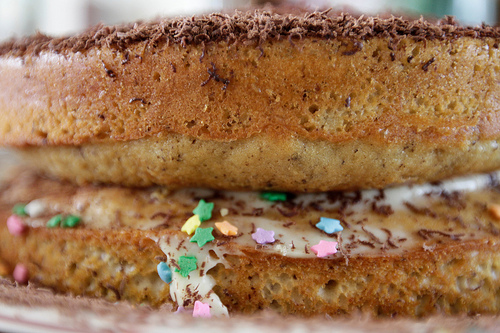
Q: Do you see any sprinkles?
A: Yes, there are sprinkles.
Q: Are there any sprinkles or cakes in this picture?
A: Yes, there are sprinkles.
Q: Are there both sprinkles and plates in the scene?
A: No, there are sprinkles but no plates.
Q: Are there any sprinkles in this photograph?
A: Yes, there are sprinkles.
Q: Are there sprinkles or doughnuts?
A: Yes, there are sprinkles.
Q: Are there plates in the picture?
A: No, there are no plates.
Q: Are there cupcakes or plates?
A: No, there are no plates or cupcakes.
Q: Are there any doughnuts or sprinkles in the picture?
A: Yes, there are sprinkles.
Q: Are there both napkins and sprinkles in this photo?
A: No, there are sprinkles but no napkins.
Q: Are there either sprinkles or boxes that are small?
A: Yes, the sprinkles are small.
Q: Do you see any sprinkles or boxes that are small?
A: Yes, the sprinkles are small.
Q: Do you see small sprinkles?
A: Yes, there are small sprinkles.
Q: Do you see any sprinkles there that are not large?
A: Yes, there are small sprinkles.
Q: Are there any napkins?
A: No, there are no napkins.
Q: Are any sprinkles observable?
A: Yes, there are sprinkles.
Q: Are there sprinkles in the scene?
A: Yes, there are sprinkles.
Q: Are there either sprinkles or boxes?
A: Yes, there are sprinkles.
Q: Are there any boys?
A: No, there are no boys.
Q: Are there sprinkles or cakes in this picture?
A: Yes, there are sprinkles.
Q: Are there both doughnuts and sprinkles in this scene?
A: No, there are sprinkles but no donuts.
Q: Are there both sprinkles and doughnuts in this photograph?
A: No, there are sprinkles but no donuts.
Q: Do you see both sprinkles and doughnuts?
A: No, there are sprinkles but no donuts.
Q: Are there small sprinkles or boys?
A: Yes, there are small sprinkles.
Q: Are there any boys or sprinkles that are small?
A: Yes, the sprinkles are small.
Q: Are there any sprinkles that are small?
A: Yes, there are small sprinkles.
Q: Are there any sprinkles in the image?
A: Yes, there are sprinkles.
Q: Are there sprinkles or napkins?
A: Yes, there are sprinkles.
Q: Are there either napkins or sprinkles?
A: Yes, there are sprinkles.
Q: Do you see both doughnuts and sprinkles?
A: No, there are sprinkles but no donuts.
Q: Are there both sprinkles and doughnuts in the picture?
A: No, there are sprinkles but no donuts.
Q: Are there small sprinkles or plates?
A: Yes, there are small sprinkles.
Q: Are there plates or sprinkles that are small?
A: Yes, the sprinkles are small.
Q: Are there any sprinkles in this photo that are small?
A: Yes, there are sprinkles that are small.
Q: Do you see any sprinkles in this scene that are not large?
A: Yes, there are small sprinkles.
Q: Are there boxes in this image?
A: No, there are no boxes.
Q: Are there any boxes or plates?
A: No, there are no boxes or plates.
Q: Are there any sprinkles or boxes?
A: Yes, there are sprinkles.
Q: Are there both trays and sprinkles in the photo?
A: No, there are sprinkles but no trays.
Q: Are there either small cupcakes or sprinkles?
A: Yes, there are small sprinkles.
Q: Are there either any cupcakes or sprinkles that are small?
A: Yes, the sprinkles are small.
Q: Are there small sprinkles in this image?
A: Yes, there are small sprinkles.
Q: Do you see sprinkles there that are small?
A: Yes, there are sprinkles that are small.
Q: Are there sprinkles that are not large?
A: Yes, there are small sprinkles.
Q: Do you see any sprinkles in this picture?
A: Yes, there are sprinkles.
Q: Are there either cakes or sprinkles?
A: Yes, there are sprinkles.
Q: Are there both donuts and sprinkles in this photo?
A: No, there are sprinkles but no donuts.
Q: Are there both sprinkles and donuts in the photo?
A: No, there are sprinkles but no donuts.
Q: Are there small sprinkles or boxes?
A: Yes, there are small sprinkles.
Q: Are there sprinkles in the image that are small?
A: Yes, there are small sprinkles.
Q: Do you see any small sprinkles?
A: Yes, there are small sprinkles.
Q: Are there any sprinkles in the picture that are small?
A: Yes, there are sprinkles that are small.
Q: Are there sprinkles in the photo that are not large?
A: Yes, there are small sprinkles.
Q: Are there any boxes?
A: No, there are no boxes.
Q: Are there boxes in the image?
A: No, there are no boxes.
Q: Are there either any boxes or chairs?
A: No, there are no boxes or chairs.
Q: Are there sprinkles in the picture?
A: Yes, there are sprinkles.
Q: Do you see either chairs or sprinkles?
A: Yes, there are sprinkles.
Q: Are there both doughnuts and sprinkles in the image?
A: No, there are sprinkles but no donuts.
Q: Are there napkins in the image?
A: No, there are no napkins.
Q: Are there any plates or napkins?
A: No, there are no napkins or plates.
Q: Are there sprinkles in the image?
A: Yes, there are sprinkles.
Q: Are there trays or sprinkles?
A: Yes, there are sprinkles.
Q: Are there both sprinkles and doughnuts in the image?
A: No, there are sprinkles but no donuts.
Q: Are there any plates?
A: No, there are no plates.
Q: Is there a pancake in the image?
A: Yes, there is a pancake.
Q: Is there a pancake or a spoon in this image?
A: Yes, there is a pancake.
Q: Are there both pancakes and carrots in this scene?
A: No, there is a pancake but no carrots.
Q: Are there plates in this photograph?
A: No, there are no plates.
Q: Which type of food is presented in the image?
A: The food is a pancake.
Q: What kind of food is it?
A: The food is a pancake.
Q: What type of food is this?
A: This is a pancake.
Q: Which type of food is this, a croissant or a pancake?
A: This is a pancake.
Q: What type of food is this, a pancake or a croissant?
A: This is a pancake.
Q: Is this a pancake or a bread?
A: This is a pancake.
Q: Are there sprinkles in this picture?
A: Yes, there are sprinkles.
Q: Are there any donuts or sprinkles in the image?
A: Yes, there are sprinkles.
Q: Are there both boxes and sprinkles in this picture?
A: No, there are sprinkles but no boxes.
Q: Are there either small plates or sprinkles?
A: Yes, there are small sprinkles.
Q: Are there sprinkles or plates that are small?
A: Yes, the sprinkles are small.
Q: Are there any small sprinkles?
A: Yes, there are small sprinkles.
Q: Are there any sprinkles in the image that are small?
A: Yes, there are small sprinkles.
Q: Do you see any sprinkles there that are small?
A: Yes, there are sprinkles that are small.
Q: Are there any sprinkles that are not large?
A: Yes, there are small sprinkles.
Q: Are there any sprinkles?
A: Yes, there are sprinkles.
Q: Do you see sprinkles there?
A: Yes, there are sprinkles.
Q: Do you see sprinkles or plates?
A: Yes, there are sprinkles.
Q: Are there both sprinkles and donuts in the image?
A: No, there are sprinkles but no donuts.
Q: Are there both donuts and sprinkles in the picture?
A: No, there are sprinkles but no donuts.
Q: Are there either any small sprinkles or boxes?
A: Yes, there are small sprinkles.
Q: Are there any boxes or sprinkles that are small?
A: Yes, the sprinkles are small.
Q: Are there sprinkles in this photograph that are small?
A: Yes, there are sprinkles that are small.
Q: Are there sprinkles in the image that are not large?
A: Yes, there are small sprinkles.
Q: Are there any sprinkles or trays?
A: Yes, there are sprinkles.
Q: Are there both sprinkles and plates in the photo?
A: No, there are sprinkles but no plates.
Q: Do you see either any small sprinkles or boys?
A: Yes, there are small sprinkles.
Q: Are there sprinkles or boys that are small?
A: Yes, the sprinkles are small.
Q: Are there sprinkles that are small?
A: Yes, there are sprinkles that are small.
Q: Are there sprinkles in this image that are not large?
A: Yes, there are small sprinkles.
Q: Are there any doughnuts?
A: No, there are no doughnuts.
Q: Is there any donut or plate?
A: No, there are no donuts or plates.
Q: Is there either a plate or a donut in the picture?
A: No, there are no donuts or plates.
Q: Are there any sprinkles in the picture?
A: Yes, there are sprinkles.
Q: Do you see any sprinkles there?
A: Yes, there are sprinkles.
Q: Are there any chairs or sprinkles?
A: Yes, there are sprinkles.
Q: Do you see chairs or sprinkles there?
A: Yes, there are sprinkles.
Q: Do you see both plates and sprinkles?
A: No, there are sprinkles but no plates.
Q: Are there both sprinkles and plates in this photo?
A: No, there are sprinkles but no plates.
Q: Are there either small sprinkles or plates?
A: Yes, there are small sprinkles.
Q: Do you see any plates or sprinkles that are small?
A: Yes, the sprinkles are small.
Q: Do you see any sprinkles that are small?
A: Yes, there are sprinkles that are small.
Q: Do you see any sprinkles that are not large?
A: Yes, there are small sprinkles.